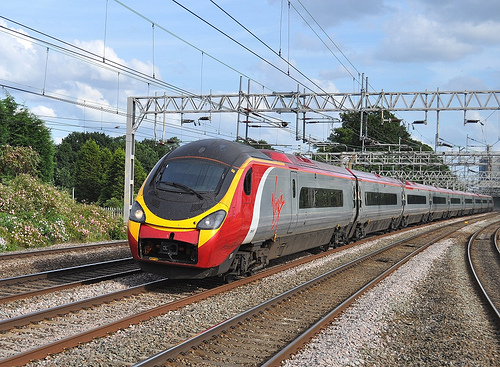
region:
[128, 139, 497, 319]
train is on tracks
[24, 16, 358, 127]
wires are above train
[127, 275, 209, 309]
gravel is under train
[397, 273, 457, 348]
gravel is near tracks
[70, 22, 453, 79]
sky is blue with clouds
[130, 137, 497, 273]
train is long and colorful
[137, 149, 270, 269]
front of train is red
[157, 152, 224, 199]
windshield is in front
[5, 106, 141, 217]
trees a near train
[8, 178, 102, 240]
flowers are near train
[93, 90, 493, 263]
silver train moving through countryside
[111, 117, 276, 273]
yellow, orange and white swirls on front part of train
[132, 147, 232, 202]
tinted panel for wide window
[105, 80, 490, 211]
train passing under metal structures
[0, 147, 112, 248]
flowering plants to side of train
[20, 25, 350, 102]
parallel wires connected to form rectangles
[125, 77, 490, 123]
zigzagging across top beam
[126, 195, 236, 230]
headlights shining on triangular panels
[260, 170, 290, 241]
red writing on side of first car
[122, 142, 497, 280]
several train cars following lead car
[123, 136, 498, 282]
a long passenger train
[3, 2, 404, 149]
power lines in the sky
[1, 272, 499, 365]
four sets of train tracks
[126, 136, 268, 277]
red, yellow and black front of train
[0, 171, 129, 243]
bushes with pink flowers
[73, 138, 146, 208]
a few green pine trees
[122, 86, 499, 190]
metal grids holding power lines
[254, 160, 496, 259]
side of train is grey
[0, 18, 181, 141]
fluffy clouds in sky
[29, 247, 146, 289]
shadow of the train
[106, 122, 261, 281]
The front of the train is red, yellow and black.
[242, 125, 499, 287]
The back of the train is grey.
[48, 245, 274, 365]
Train is driving on tracks.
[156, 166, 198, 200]
Windshield wiper of the train.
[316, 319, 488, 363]
Gravel between the tracks.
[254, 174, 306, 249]
Writing on the train.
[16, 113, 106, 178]
The trees are green.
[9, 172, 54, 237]
Flowers in the bushes.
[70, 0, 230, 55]
The sky is blue.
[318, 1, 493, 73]
Grey clouds in the sky.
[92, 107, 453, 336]
Train on the rails.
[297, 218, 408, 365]
Rails under the train.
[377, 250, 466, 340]
Rocks on the tracks.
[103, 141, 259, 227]
Window on the train.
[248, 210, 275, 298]
Wheels on the train.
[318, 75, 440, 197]
Tree behind the train.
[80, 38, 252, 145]
Power lines above the train.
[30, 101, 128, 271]
Bushes below the trees.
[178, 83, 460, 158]
Metal over the train.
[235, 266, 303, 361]
Metal tracks on the ground.